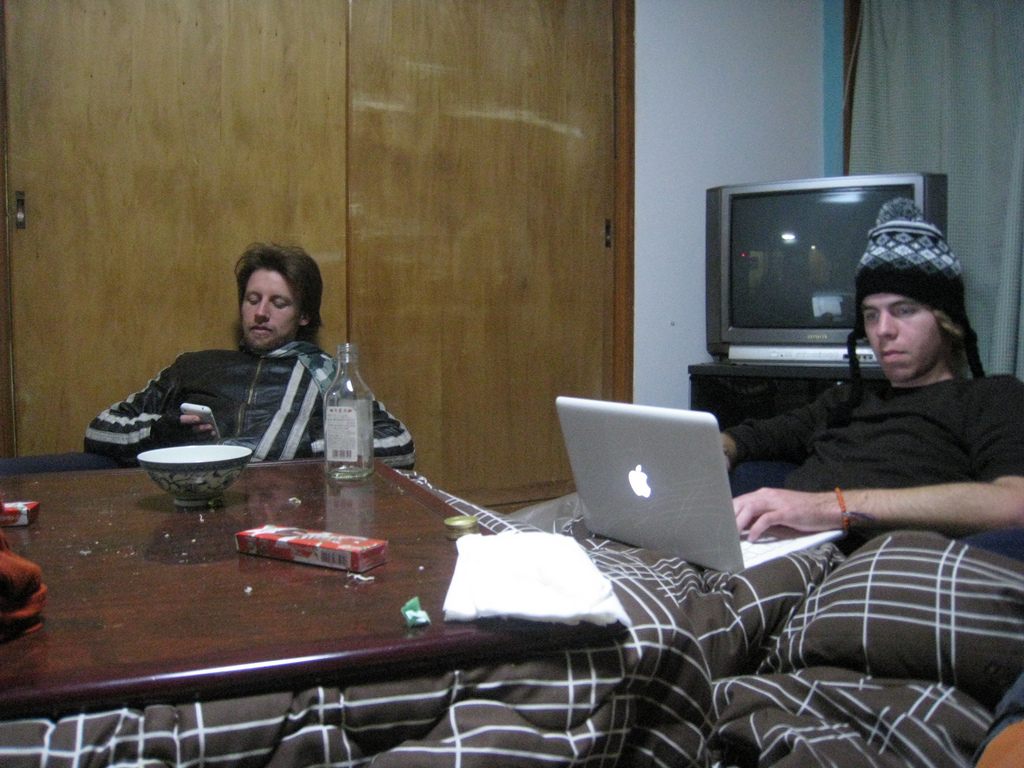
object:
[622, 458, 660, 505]
apple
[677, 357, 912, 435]
table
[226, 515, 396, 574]
cigarette box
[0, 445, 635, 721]
table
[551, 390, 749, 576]
back lid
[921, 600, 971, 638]
lap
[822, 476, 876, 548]
bracelet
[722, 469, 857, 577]
hand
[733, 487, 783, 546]
finger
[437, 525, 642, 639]
napkin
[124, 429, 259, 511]
bowl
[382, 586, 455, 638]
garbage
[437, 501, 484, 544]
garbage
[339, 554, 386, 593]
garbage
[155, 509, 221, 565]
garbage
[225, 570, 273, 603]
garbage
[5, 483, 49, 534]
garbage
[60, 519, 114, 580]
garbage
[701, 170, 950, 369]
television set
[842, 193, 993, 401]
bonnet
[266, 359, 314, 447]
stripes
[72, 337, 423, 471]
jacket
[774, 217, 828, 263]
reflection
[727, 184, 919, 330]
tv screen